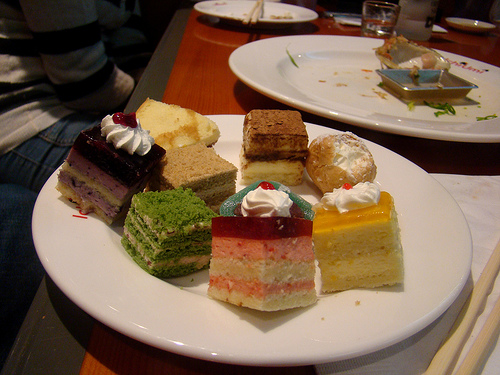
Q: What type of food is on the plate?
A: Cake.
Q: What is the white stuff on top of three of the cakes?
A: Whipped cream.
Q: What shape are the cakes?
A: Squares.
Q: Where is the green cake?
A: Between the purple and red one.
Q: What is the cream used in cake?
A: Whip cream.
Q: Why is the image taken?
A: Rememberance.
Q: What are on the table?
A: Chopsticks.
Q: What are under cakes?
A: White plates.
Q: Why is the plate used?
A: To keep items.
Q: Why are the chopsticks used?
A: To hold the item to eat.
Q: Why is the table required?
A: To sit.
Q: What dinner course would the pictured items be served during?
A: Dessert.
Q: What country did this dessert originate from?
A: France.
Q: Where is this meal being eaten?
A: Restaurant.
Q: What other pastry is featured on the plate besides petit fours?
A: Cream puff.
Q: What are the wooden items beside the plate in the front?
A: Chopsticks.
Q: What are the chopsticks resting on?
A: Napkin.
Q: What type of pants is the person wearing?
A: Blue jeans.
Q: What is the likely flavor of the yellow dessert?
A: Lemon.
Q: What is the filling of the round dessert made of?
A: Cream.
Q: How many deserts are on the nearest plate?
A: Nine.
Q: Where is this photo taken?
A: A restaurant.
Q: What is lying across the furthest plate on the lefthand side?
A: Chopsticks.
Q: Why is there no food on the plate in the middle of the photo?
A: It was eaten.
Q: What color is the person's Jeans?
A: Blue.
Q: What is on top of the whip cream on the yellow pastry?
A: A Cherry.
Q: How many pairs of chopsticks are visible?
A: Two.